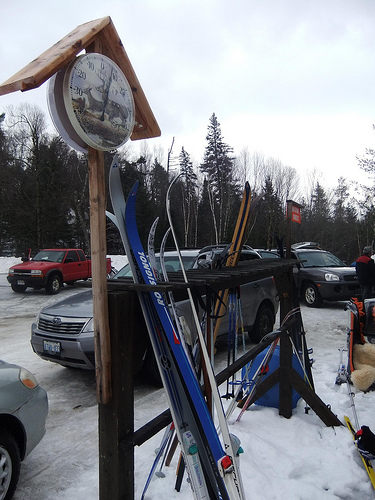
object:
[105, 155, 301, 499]
skis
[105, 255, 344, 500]
rack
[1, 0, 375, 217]
sky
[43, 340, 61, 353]
license plate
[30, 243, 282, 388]
car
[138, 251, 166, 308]
logo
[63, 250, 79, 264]
window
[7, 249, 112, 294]
car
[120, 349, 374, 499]
snow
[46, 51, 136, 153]
clock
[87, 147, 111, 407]
post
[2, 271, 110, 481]
street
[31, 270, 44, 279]
light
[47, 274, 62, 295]
tire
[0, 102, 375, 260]
trees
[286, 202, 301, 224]
sign